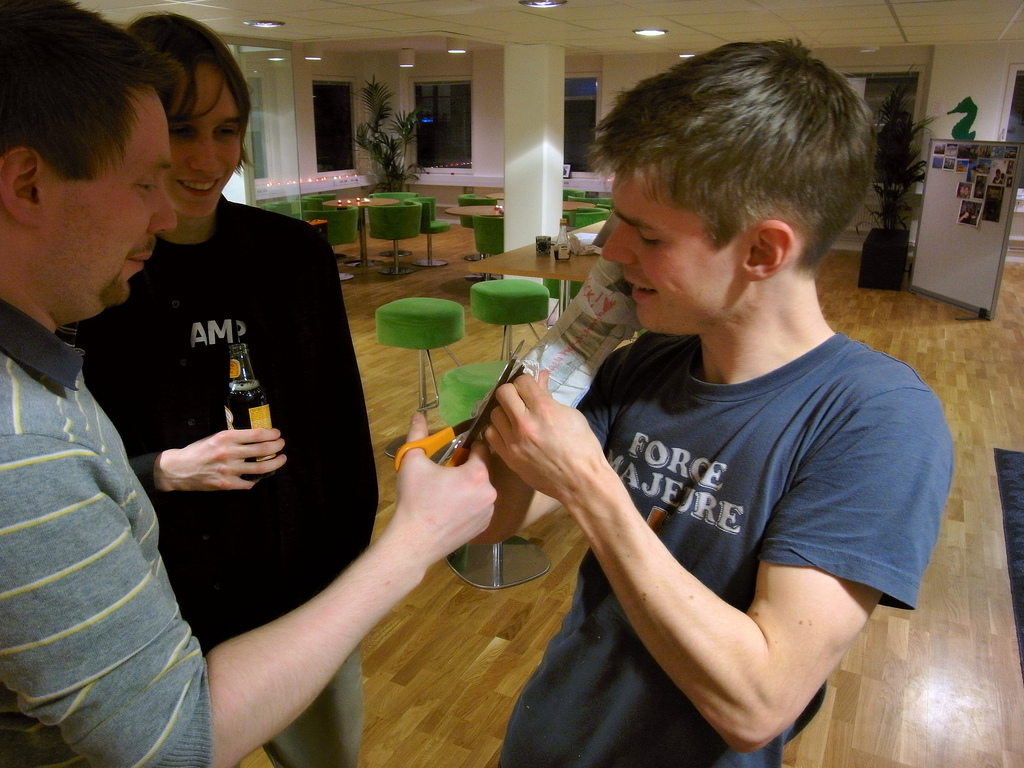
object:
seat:
[466, 275, 554, 329]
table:
[321, 178, 409, 290]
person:
[60, 12, 384, 767]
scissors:
[386, 335, 546, 477]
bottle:
[195, 339, 299, 481]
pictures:
[896, 121, 1020, 255]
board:
[896, 121, 1022, 322]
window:
[412, 78, 480, 173]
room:
[88, 0, 1024, 644]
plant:
[334, 82, 430, 178]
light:
[254, 0, 287, 33]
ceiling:
[232, 0, 1009, 72]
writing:
[580, 432, 758, 547]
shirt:
[508, 332, 952, 733]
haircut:
[0, 0, 158, 182]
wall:
[920, 22, 1012, 139]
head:
[587, 38, 897, 270]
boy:
[485, 36, 960, 753]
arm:
[562, 445, 830, 752]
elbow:
[703, 638, 839, 755]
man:
[475, 32, 961, 759]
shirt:
[8, 323, 218, 703]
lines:
[0, 437, 218, 767]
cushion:
[375, 293, 467, 347]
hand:
[146, 415, 290, 497]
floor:
[950, 312, 986, 755]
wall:
[258, 48, 501, 185]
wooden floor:
[395, 599, 501, 764]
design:
[600, 419, 742, 539]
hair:
[592, 31, 873, 241]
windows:
[309, 72, 361, 172]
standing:
[469, 37, 949, 764]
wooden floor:
[873, 606, 994, 764]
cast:
[514, 258, 638, 408]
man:
[5, 4, 224, 767]